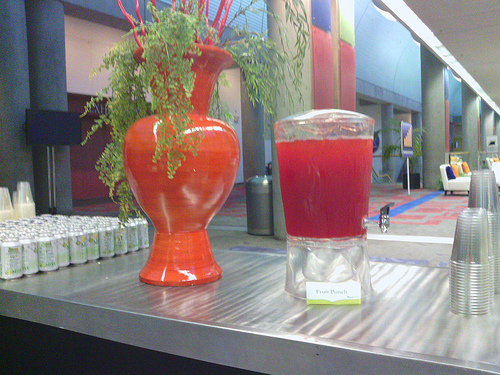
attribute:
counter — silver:
[2, 224, 495, 356]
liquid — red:
[280, 136, 368, 241]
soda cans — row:
[0, 239, 25, 281]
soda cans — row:
[20, 237, 41, 279]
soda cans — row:
[33, 237, 60, 272]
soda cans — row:
[56, 233, 71, 268]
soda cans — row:
[67, 232, 89, 268]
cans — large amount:
[2, 212, 150, 289]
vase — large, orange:
[108, 39, 243, 294]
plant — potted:
[93, 0, 280, 194]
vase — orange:
[117, 110, 264, 267]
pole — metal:
[403, 155, 412, 193]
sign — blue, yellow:
[399, 117, 416, 157]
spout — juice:
[361, 200, 393, 230]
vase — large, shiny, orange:
[116, 38, 247, 285]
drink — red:
[272, 116, 372, 252]